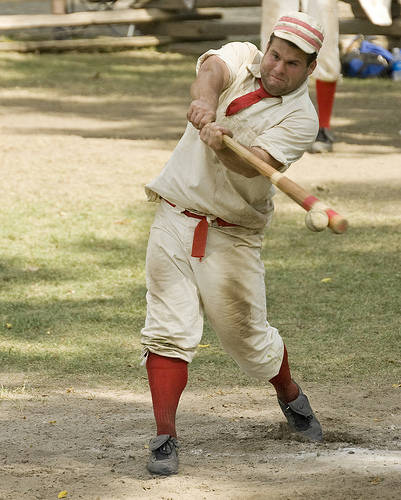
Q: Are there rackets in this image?
A: No, there are no rackets.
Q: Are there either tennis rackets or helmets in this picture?
A: No, there are no tennis rackets or helmets.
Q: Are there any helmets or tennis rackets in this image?
A: No, there are no tennis rackets or helmets.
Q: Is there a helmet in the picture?
A: No, there are no helmets.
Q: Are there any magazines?
A: No, there are no magazines.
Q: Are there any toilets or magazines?
A: No, there are no magazines or toilets.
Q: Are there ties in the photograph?
A: Yes, there is a tie.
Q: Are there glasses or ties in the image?
A: Yes, there is a tie.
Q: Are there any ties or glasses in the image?
A: Yes, there is a tie.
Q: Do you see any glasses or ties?
A: Yes, there is a tie.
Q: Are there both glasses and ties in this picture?
A: No, there is a tie but no glasses.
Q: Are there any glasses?
A: No, there are no glasses.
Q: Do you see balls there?
A: Yes, there is a ball.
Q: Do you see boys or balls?
A: Yes, there is a ball.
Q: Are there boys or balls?
A: Yes, there is a ball.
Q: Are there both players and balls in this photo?
A: Yes, there are both a ball and a player.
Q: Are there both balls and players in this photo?
A: Yes, there are both a ball and a player.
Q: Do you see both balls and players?
A: Yes, there are both a ball and a player.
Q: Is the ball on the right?
A: Yes, the ball is on the right of the image.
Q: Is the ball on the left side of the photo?
A: No, the ball is on the right of the image.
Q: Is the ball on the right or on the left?
A: The ball is on the right of the image.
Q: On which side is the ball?
A: The ball is on the right of the image.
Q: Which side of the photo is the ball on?
A: The ball is on the right of the image.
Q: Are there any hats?
A: Yes, there is a hat.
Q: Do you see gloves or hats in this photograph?
A: Yes, there is a hat.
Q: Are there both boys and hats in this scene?
A: No, there is a hat but no boys.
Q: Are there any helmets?
A: No, there are no helmets.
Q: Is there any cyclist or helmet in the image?
A: No, there are no helmets or cyclists.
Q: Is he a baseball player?
A: Yes, this is a baseball player.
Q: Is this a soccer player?
A: No, this is a baseball player.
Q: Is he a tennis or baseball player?
A: This is a baseball player.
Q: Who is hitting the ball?
A: The player is hitting the ball.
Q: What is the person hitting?
A: The player is hitting the ball.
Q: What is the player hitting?
A: The player is hitting the ball.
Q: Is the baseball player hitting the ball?
A: Yes, the player is hitting the ball.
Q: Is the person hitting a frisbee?
A: No, the player is hitting the ball.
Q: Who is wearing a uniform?
A: The player is wearing a uniform.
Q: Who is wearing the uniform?
A: The player is wearing a uniform.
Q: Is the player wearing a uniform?
A: Yes, the player is wearing a uniform.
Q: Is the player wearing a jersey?
A: No, the player is wearing a uniform.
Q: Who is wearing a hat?
A: The player is wearing a hat.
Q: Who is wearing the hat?
A: The player is wearing a hat.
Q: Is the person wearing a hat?
A: Yes, the player is wearing a hat.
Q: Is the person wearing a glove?
A: No, the player is wearing a hat.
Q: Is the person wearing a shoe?
A: Yes, the player is wearing a shoe.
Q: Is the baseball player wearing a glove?
A: No, the player is wearing a shoe.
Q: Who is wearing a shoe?
A: The player is wearing a shoe.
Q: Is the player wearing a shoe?
A: Yes, the player is wearing a shoe.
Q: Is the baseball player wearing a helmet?
A: No, the player is wearing a shoe.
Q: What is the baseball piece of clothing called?
A: The clothing item is a uniform.